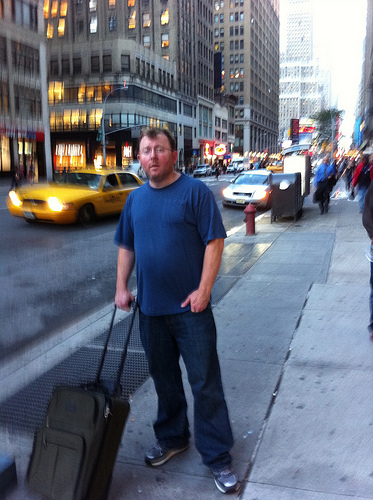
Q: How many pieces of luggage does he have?
A: One.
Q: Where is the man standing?
A: On the sidewalk.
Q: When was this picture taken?
A: Daytime.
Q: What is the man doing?
A: Standing.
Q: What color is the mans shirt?
A: Blue.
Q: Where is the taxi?
A: On the street.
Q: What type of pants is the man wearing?
A: Jeans.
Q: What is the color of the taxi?
A: Yellow.